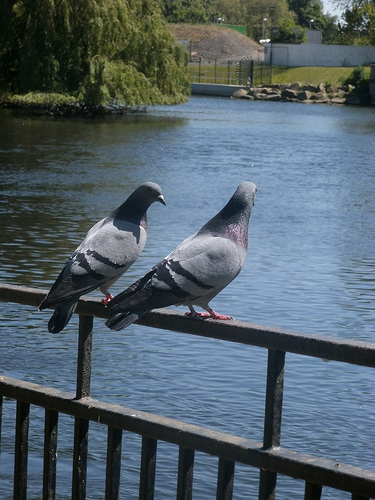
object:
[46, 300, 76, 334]
tail feather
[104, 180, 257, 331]
pigeon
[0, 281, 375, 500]
metal rail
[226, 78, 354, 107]
rock pile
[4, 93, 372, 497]
water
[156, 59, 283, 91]
fence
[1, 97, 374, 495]
lake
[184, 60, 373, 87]
hill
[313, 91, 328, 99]
rock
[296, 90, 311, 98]
rock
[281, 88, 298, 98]
rock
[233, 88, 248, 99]
rock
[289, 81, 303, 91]
rock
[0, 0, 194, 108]
trees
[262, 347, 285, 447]
bar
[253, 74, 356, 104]
gray pile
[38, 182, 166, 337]
bird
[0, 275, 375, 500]
rail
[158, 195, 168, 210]
beak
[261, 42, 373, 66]
white wall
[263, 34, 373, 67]
building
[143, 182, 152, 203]
eye